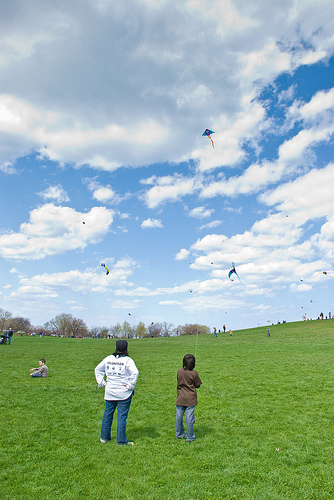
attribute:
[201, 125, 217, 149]
kite — blue, orange, purple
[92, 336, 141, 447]
woman — watching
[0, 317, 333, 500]
grass — long, green, well tended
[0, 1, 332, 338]
sky — blue, cloudy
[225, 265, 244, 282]
kite — curved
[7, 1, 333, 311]
clouds — white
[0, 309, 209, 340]
trees — brown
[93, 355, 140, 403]
shirt — white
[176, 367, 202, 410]
shirt — brown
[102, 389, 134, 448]
jeans — blue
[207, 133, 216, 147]
tail — yellow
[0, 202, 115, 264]
cloud — floating